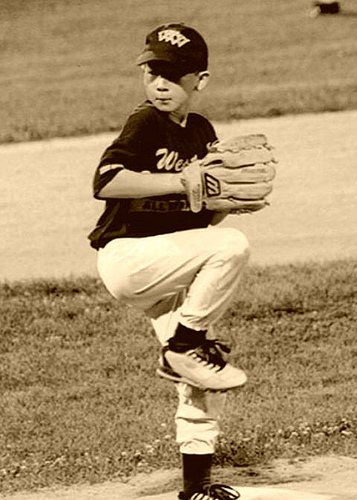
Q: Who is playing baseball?
A: A kid.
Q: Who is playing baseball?
A: A boy.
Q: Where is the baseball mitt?
A: On hand.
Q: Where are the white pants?
A: On kid.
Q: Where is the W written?
A: On shirt.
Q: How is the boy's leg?
A: Raised.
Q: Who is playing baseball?
A: A boy.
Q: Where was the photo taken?
A: At a baseball field.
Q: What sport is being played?
A: Baseball.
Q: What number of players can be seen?
A: One.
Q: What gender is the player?
A: Male.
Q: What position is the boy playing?
A: Pitcher.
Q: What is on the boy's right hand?
A: A baseball glove.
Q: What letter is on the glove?
A: M.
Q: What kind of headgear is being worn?
A: A cap.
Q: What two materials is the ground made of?
A: Grass and dirt.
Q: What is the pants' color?
A: White.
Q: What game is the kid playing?
A: Baseball.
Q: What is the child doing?
A: Playing baseball.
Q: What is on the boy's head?
A: A hat.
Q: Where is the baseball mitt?
A: On the boy's hand.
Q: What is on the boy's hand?
A: Catcher's mitt.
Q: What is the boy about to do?
A: Throw a baseball.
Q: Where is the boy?
A: On a baseball field.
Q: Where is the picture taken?
A: Baseball field.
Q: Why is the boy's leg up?
A: He is getting ready to throw the ball.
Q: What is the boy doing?
A: Pitching a baseball.